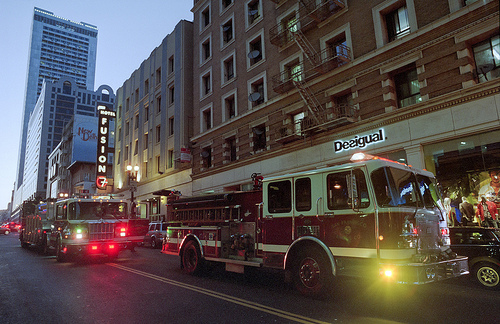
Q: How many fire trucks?
A: 2.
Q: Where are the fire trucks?
A: In street.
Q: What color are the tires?
A: Black.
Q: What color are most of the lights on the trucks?
A: Red.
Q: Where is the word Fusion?
A: On black sign.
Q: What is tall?
A: Buildings.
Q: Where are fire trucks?
A: In the street.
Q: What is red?
A: Lights.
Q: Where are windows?
A: On buildings.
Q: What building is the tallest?
A: White building on left.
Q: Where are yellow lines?
A: On the street.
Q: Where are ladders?
A: On brown building.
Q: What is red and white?
A: Fire Truck.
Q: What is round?
A: Tires.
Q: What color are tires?
A: Black.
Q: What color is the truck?
A: Red and white.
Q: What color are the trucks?
A: Red.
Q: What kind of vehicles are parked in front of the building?
A: Firetrucks.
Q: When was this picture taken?
A: Dusk.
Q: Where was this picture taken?
A: City.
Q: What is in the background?
A: Buildings.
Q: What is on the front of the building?
A: Fire escape.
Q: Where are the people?
A: Behind the tucks.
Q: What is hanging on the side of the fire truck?
A: Ladder.